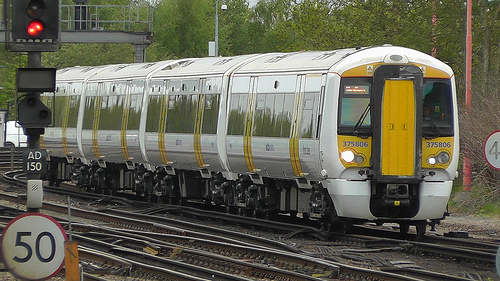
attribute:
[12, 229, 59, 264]
numbers — black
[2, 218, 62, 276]
background — white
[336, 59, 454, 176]
front — yellow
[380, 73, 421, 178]
rectangle — yellow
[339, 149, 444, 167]
lights — white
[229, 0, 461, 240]
train — yellow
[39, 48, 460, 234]
train — white, yellow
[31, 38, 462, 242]
train — white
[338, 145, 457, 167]
lights — bright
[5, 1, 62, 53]
signal — black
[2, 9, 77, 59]
light — red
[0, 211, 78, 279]
sign — red, white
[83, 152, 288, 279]
tracks — steel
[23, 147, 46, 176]
sign — black